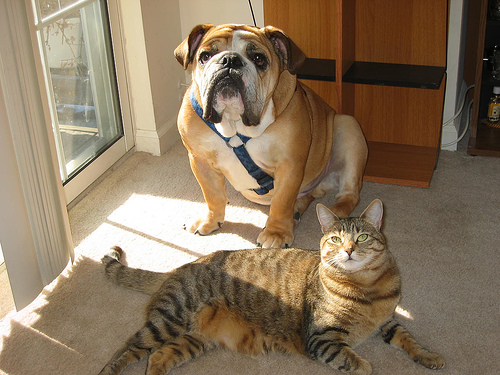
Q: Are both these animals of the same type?
A: No, they are dogs and cats.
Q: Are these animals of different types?
A: Yes, they are dogs and cats.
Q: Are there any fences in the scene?
A: No, there are no fences.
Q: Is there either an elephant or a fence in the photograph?
A: No, there are no fences or elephants.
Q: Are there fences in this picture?
A: No, there are no fences.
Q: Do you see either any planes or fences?
A: No, there are no fences or planes.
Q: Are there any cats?
A: Yes, there is a cat.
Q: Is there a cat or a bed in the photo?
A: Yes, there is a cat.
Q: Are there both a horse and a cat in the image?
A: No, there is a cat but no horses.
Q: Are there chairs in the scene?
A: No, there are no chairs.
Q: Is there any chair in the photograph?
A: No, there are no chairs.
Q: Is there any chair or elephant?
A: No, there are no chairs or elephants.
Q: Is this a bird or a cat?
A: This is a cat.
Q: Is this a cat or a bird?
A: This is a cat.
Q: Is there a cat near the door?
A: Yes, there is a cat near the door.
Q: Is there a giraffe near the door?
A: No, there is a cat near the door.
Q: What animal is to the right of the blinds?
A: The animal is a cat.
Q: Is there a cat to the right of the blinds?
A: Yes, there is a cat to the right of the blinds.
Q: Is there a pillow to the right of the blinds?
A: No, there is a cat to the right of the blinds.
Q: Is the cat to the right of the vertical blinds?
A: Yes, the cat is to the right of the blinds.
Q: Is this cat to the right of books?
A: No, the cat is to the right of the blinds.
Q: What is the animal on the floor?
A: The animal is a cat.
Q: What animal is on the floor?
A: The animal is a cat.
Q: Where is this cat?
A: The cat is on the floor.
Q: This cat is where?
A: The cat is on the floor.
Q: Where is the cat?
A: The cat is on the floor.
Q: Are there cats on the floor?
A: Yes, there is a cat on the floor.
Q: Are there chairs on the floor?
A: No, there is a cat on the floor.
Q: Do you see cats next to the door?
A: Yes, there is a cat next to the door.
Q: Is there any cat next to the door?
A: Yes, there is a cat next to the door.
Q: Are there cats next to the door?
A: Yes, there is a cat next to the door.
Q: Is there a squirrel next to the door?
A: No, there is a cat next to the door.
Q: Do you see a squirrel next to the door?
A: No, there is a cat next to the door.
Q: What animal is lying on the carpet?
A: The cat is lying on the carpet.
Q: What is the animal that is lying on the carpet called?
A: The animal is a cat.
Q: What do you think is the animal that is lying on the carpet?
A: The animal is a cat.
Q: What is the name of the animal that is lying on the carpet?
A: The animal is a cat.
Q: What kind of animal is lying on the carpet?
A: The animal is a cat.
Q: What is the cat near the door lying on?
A: The cat is lying on the carpet.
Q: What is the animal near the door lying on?
A: The cat is lying on the carpet.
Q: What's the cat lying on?
A: The cat is lying on the carpet.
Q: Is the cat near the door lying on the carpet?
A: Yes, the cat is lying on the carpet.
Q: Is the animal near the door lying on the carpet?
A: Yes, the cat is lying on the carpet.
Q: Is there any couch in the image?
A: No, there are no couches.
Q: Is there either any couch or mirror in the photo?
A: No, there are no couches or mirrors.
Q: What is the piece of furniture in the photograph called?
A: The piece of furniture is a shelf.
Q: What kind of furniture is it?
A: The piece of furniture is a shelf.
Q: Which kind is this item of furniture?
A: This is a shelf.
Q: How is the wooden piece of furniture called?
A: The piece of furniture is a shelf.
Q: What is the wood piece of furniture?
A: The piece of furniture is a shelf.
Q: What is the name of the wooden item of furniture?
A: The piece of furniture is a shelf.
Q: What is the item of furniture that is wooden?
A: The piece of furniture is a shelf.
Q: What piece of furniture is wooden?
A: The piece of furniture is a shelf.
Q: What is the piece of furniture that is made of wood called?
A: The piece of furniture is a shelf.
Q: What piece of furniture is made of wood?
A: The piece of furniture is a shelf.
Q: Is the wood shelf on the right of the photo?
A: Yes, the shelf is on the right of the image.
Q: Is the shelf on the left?
A: No, the shelf is on the right of the image.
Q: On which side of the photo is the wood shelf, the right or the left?
A: The shelf is on the right of the image.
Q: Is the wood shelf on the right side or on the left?
A: The shelf is on the right of the image.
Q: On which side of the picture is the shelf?
A: The shelf is on the right of the image.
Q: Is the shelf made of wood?
A: Yes, the shelf is made of wood.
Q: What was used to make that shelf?
A: The shelf is made of wood.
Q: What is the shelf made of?
A: The shelf is made of wood.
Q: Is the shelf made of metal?
A: No, the shelf is made of wood.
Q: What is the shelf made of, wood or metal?
A: The shelf is made of wood.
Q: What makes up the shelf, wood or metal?
A: The shelf is made of wood.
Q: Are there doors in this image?
A: Yes, there is a door.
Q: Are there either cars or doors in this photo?
A: Yes, there is a door.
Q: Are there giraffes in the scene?
A: No, there are no giraffes.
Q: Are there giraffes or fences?
A: No, there are no giraffes or fences.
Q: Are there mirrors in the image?
A: No, there are no mirrors.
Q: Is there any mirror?
A: No, there are no mirrors.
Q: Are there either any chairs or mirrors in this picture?
A: No, there are no mirrors or chairs.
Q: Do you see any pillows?
A: No, there are no pillows.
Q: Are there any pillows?
A: No, there are no pillows.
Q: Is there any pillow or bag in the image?
A: No, there are no pillows or bags.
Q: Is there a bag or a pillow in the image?
A: No, there are no pillows or bags.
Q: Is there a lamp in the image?
A: No, there are no lamps.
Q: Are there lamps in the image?
A: No, there are no lamps.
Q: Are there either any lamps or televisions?
A: No, there are no lamps or televisions.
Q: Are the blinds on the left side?
A: Yes, the blinds are on the left of the image.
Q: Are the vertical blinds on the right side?
A: No, the blinds are on the left of the image.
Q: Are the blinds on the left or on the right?
A: The blinds are on the left of the image.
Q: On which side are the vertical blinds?
A: The blinds are on the left of the image.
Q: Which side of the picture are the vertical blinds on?
A: The blinds are on the left of the image.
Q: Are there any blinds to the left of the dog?
A: Yes, there are blinds to the left of the dog.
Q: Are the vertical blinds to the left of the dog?
A: Yes, the blinds are to the left of the dog.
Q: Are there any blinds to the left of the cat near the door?
A: Yes, there are blinds to the left of the cat.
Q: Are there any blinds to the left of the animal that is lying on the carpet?
A: Yes, there are blinds to the left of the cat.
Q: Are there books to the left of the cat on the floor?
A: No, there are blinds to the left of the cat.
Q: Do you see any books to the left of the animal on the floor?
A: No, there are blinds to the left of the cat.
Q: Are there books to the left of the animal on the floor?
A: No, there are blinds to the left of the cat.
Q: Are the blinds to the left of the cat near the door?
A: Yes, the blinds are to the left of the cat.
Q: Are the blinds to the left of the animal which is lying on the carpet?
A: Yes, the blinds are to the left of the cat.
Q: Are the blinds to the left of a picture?
A: No, the blinds are to the left of the cat.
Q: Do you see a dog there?
A: Yes, there is a dog.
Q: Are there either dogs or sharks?
A: Yes, there is a dog.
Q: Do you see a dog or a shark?
A: Yes, there is a dog.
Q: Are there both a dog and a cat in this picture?
A: Yes, there are both a dog and a cat.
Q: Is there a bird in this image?
A: No, there are no birds.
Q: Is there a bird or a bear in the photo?
A: No, there are no birds or bears.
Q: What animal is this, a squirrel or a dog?
A: This is a dog.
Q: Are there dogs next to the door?
A: Yes, there is a dog next to the door.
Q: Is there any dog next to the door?
A: Yes, there is a dog next to the door.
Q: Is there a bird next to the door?
A: No, there is a dog next to the door.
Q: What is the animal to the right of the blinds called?
A: The animal is a dog.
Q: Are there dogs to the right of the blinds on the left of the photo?
A: Yes, there is a dog to the right of the blinds.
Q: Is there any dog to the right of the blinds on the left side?
A: Yes, there is a dog to the right of the blinds.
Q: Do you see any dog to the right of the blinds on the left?
A: Yes, there is a dog to the right of the blinds.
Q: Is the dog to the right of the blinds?
A: Yes, the dog is to the right of the blinds.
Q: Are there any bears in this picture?
A: No, there are no bears.